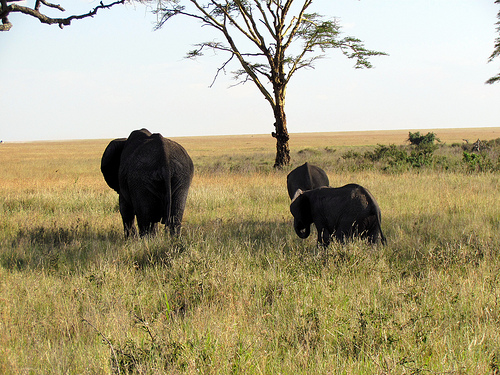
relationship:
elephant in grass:
[102, 130, 191, 248] [1, 137, 498, 375]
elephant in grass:
[278, 186, 398, 255] [1, 137, 498, 375]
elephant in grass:
[283, 161, 330, 200] [1, 137, 498, 375]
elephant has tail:
[102, 130, 191, 248] [161, 166, 175, 230]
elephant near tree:
[102, 130, 191, 248] [163, 1, 385, 171]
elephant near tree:
[278, 186, 398, 255] [163, 1, 385, 171]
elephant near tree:
[283, 161, 330, 200] [163, 1, 385, 171]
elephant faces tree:
[102, 130, 191, 248] [163, 1, 385, 171]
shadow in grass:
[29, 237, 198, 312] [95, 253, 477, 370]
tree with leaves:
[148, 3, 386, 182] [301, 12, 363, 64]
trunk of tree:
[264, 106, 296, 163] [214, 2, 329, 169]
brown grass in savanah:
[298, 134, 424, 183] [175, 106, 498, 323]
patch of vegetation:
[187, 140, 498, 181] [407, 128, 441, 151]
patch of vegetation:
[187, 140, 498, 181] [460, 140, 490, 169]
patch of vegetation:
[187, 140, 498, 181] [322, 141, 341, 157]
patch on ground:
[187, 140, 498, 181] [1, 122, 497, 373]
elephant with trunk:
[278, 186, 398, 255] [289, 218, 314, 240]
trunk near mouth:
[289, 218, 314, 240] [306, 216, 313, 226]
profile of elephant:
[286, 181, 385, 241] [278, 186, 398, 255]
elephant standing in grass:
[102, 130, 191, 248] [38, 247, 485, 348]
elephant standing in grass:
[278, 186, 398, 255] [38, 247, 485, 348]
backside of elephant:
[285, 162, 325, 192] [286, 162, 328, 199]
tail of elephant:
[300, 157, 313, 194] [286, 162, 328, 199]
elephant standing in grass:
[278, 186, 398, 255] [177, 246, 494, 355]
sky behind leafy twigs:
[0, 0, 498, 143] [481, 0, 498, 87]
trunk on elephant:
[289, 218, 314, 240] [278, 186, 398, 255]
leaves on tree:
[354, 59, 373, 69] [148, 3, 386, 182]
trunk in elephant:
[289, 218, 314, 240] [283, 171, 397, 258]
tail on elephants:
[156, 135, 178, 225] [92, 120, 193, 236]